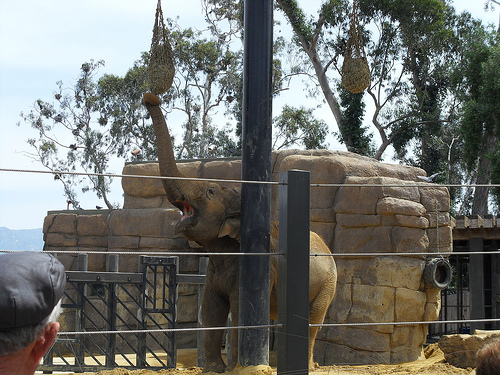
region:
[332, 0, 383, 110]
A SACK OF HAY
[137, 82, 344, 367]
a full grown elephant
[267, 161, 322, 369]
a dark brown pole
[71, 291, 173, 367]
some angled metal bars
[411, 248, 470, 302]
a large black tire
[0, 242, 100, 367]
a man wearing a hat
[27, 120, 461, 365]
a large rock formation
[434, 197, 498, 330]
wood roofing on a structure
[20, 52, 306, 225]
a tree with thin foliage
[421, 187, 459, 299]
a chain attached to a tire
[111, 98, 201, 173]
trunk of an elephant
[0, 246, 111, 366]
head of a man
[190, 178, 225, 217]
eye of the animal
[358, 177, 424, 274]
rocks behind the elephant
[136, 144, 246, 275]
head of the elephant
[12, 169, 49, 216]
sky above the land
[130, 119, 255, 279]
elephant behind a cage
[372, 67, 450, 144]
tree branches in background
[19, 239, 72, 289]
hat on the man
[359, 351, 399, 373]
dirt on the ground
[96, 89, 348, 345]
the elephant is standing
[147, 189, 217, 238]
the mouth is open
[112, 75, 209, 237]
the trunk is raised upwards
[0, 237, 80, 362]
the man is wearing a hat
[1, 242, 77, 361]
the man is looking at the elephant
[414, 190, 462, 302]
a black tire is hanging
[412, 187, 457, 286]
the tire is on a chain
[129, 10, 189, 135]
the trunk is reaching for the feeder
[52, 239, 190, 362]
a short iron gate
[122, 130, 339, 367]
the animal is dirty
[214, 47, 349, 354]
a black post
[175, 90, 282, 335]
a black post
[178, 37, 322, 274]
a black post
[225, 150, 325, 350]
a black post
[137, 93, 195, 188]
The trunk of the elephant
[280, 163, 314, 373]
A black fence post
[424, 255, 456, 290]
A tire on a chain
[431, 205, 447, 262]
A chain hanging from a rock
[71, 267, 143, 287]
A wooden rail for the fence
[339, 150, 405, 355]
Stone rock boulders.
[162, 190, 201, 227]
The mouth of the elephant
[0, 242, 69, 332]
A leather head cap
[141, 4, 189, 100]
A net hanging over the elephant head.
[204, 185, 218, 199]
The eye of an elephant